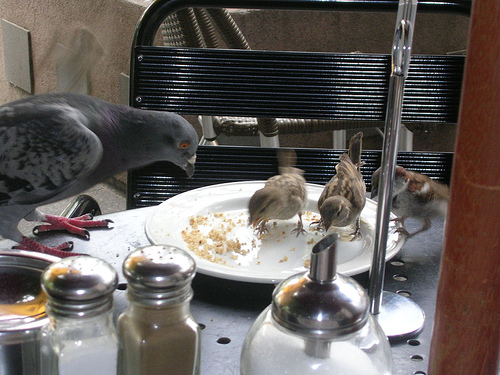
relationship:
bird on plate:
[370, 163, 452, 239] [144, 173, 402, 281]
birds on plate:
[310, 131, 367, 241] [144, 173, 402, 281]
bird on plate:
[247, 149, 307, 238] [144, 173, 402, 281]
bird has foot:
[0, 92, 199, 259] [6, 228, 91, 257]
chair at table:
[132, 10, 481, 249] [15, 192, 469, 372]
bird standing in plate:
[247, 149, 307, 238] [144, 173, 402, 281]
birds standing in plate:
[308, 127, 368, 242] [144, 173, 402, 281]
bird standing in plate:
[370, 163, 452, 239] [144, 173, 402, 281]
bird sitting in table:
[0, 92, 197, 260] [1, 205, 446, 373]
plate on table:
[142, 173, 414, 295] [442, 182, 458, 373]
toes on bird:
[12, 203, 152, 274] [16, 77, 268, 209]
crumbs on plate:
[184, 209, 249, 272] [125, 195, 210, 247]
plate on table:
[144, 180, 409, 284] [7, 170, 447, 373]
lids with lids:
[39, 255, 119, 320] [36, 239, 196, 316]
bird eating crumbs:
[247, 149, 307, 238] [175, 206, 256, 271]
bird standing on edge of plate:
[0, 92, 199, 259] [139, 167, 404, 290]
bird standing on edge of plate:
[395, 161, 452, 229] [139, 167, 404, 290]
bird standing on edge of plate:
[239, 146, 313, 236] [139, 167, 404, 290]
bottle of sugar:
[240, 270, 394, 375] [240, 325, 378, 372]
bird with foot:
[247, 149, 307, 238] [41, 203, 103, 246]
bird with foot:
[247, 149, 307, 238] [8, 232, 86, 274]